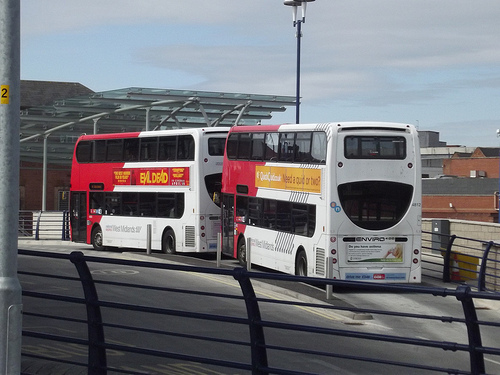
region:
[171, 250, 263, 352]
black metal rail by street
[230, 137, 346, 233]
red and white bus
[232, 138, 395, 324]
bus is double decker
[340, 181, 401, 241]
black back glass of bus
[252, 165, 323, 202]
bus is white with yellow sign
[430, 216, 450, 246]
gray receptacle in background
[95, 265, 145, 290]
white circle on street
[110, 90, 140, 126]
top of metal storage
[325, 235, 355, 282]
brake lights on bus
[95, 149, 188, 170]
black windows on bus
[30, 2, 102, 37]
white clouds in blue sky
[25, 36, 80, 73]
white clouds in blue sky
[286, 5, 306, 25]
light post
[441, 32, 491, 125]
white clouds in blue sky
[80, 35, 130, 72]
white clouds in blue sky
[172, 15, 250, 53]
white clouds in blue sky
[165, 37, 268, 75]
white clouds in blue sky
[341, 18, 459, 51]
white clouds in blue sky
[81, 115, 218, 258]
red and white bus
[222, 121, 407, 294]
red and white bus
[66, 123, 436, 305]
two double decker buses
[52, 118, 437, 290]
two buses on roadway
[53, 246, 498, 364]
railing made of metal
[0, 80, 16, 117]
Number 2 on pole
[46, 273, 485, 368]
railing is black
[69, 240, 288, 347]
road is gray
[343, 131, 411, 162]
rear windows on bus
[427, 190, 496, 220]
red brick building behind bus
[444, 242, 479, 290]
yellow bin by railing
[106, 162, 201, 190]
gold lettering on side of bus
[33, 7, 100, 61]
white clouds in blue sky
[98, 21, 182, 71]
white clouds in blue sky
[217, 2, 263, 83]
white clouds in blue sky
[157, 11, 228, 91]
white clouds in blue sky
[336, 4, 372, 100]
white clouds in blue sky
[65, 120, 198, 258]
red white and orange bus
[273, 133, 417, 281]
bus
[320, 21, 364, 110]
white clouds in blue sky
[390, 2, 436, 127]
white clouds in blue sky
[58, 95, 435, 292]
Two double decker buses.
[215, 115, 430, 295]
Front of bus on right is red.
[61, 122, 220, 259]
Front of bus on left is red.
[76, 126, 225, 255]
Back of bus on left is white.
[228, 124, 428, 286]
Back of bus on right is white.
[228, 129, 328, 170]
Passenger windows on top of bus on right.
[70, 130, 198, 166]
Passenger windows on top of bus on left.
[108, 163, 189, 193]
Advertisement on bus on the left.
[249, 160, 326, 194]
Advertisement on bus on the right.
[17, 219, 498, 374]
Black iron fence railing.